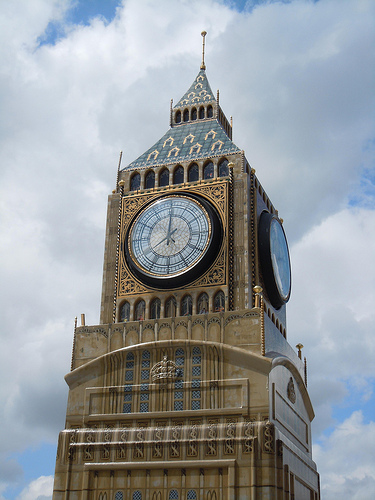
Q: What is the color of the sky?
A: Blue and white.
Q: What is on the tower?
A: Clock.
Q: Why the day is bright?
A: It's morning.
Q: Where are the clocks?
A: Top of the tower.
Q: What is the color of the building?
A: Beige.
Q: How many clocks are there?
A: Two.